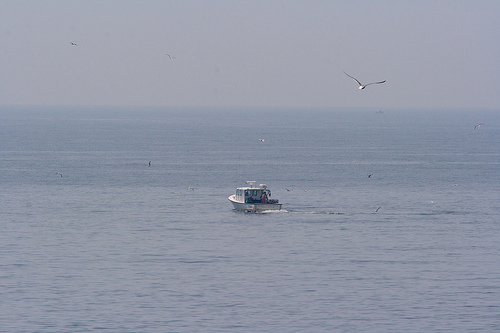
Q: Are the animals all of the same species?
A: Yes, all the animals are birds.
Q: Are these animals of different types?
A: No, all the animals are birds.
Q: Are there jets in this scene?
A: No, there are no jets.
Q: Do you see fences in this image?
A: No, there are no fences.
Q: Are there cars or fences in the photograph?
A: No, there are no fences or cars.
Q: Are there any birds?
A: Yes, there is a bird.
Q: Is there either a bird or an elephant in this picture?
A: Yes, there is a bird.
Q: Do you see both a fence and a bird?
A: No, there is a bird but no fences.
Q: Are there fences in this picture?
A: No, there are no fences.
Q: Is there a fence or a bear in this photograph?
A: No, there are no fences or bears.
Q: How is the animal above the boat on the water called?
A: The animal is a bird.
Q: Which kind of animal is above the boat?
A: The animal is a bird.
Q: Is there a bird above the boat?
A: Yes, there is a bird above the boat.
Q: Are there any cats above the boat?
A: No, there is a bird above the boat.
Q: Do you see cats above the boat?
A: No, there is a bird above the boat.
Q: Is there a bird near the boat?
A: Yes, there is a bird near the boat.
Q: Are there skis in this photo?
A: No, there are no skis.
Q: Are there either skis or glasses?
A: No, there are no skis or glasses.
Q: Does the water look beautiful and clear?
A: Yes, the water is beautiful and clear.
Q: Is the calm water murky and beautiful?
A: No, the water is beautiful but clear.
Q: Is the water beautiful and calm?
A: Yes, the water is beautiful and calm.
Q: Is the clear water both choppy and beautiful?
A: No, the water is beautiful but calm.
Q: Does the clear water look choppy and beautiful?
A: No, the water is beautiful but calm.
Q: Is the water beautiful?
A: Yes, the water is beautiful.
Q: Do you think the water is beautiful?
A: Yes, the water is beautiful.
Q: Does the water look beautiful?
A: Yes, the water is beautiful.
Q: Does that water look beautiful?
A: Yes, the water is beautiful.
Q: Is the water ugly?
A: No, the water is beautiful.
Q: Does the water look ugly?
A: No, the water is beautiful.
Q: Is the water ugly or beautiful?
A: The water is beautiful.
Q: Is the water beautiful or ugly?
A: The water is beautiful.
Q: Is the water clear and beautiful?
A: Yes, the water is clear and beautiful.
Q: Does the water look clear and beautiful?
A: Yes, the water is clear and beautiful.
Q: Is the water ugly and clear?
A: No, the water is clear but beautiful.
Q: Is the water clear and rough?
A: No, the water is clear but calm.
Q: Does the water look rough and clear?
A: No, the water is clear but calm.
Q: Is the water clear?
A: Yes, the water is clear.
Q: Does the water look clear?
A: Yes, the water is clear.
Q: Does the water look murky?
A: No, the water is clear.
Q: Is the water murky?
A: No, the water is clear.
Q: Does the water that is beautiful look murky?
A: No, the water is clear.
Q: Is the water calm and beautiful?
A: Yes, the water is calm and beautiful.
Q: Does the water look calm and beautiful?
A: Yes, the water is calm and beautiful.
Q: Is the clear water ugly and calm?
A: No, the water is calm but beautiful.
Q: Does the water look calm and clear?
A: Yes, the water is calm and clear.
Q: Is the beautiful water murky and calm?
A: No, the water is calm but clear.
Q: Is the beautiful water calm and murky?
A: No, the water is calm but clear.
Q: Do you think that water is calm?
A: Yes, the water is calm.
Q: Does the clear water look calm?
A: Yes, the water is calm.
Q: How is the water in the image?
A: The water is calm.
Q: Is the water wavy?
A: No, the water is calm.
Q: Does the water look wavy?
A: No, the water is calm.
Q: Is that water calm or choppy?
A: The water is calm.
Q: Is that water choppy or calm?
A: The water is calm.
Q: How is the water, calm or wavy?
A: The water is calm.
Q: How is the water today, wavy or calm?
A: The water is calm.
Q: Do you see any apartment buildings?
A: No, there are no apartment buildings.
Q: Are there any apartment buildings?
A: No, there are no apartment buildings.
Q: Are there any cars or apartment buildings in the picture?
A: No, there are no apartment buildings or cars.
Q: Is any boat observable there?
A: Yes, there is a boat.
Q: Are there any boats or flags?
A: Yes, there is a boat.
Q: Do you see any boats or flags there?
A: Yes, there is a boat.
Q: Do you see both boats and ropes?
A: No, there is a boat but no ropes.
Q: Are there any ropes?
A: No, there are no ropes.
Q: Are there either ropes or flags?
A: No, there are no ropes or flags.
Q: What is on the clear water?
A: The boat is on the water.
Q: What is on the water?
A: The boat is on the water.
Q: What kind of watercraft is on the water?
A: The watercraft is a boat.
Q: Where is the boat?
A: The boat is on the water.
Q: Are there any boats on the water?
A: Yes, there is a boat on the water.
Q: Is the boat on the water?
A: Yes, the boat is on the water.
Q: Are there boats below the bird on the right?
A: Yes, there is a boat below the bird.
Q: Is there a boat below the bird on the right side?
A: Yes, there is a boat below the bird.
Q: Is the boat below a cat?
A: No, the boat is below the bird.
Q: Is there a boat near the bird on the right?
A: Yes, there is a boat near the bird.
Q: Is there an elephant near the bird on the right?
A: No, there is a boat near the bird.